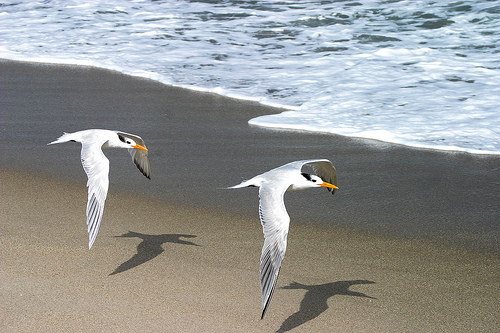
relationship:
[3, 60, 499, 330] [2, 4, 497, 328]
sand on beach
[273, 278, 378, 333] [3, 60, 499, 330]
shadow on sand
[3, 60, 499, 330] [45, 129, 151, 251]
sand under bird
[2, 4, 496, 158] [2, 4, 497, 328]
waves on beach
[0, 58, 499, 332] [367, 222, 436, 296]
sand on beach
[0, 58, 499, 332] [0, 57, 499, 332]
sand on beach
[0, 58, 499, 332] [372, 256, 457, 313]
sand on beach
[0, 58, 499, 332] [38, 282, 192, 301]
sand on beach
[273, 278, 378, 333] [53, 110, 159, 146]
shadow of a bird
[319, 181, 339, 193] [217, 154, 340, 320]
beak of a bird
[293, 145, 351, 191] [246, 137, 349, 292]
wing of a bird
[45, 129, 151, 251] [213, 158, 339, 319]
bird ahead of bird